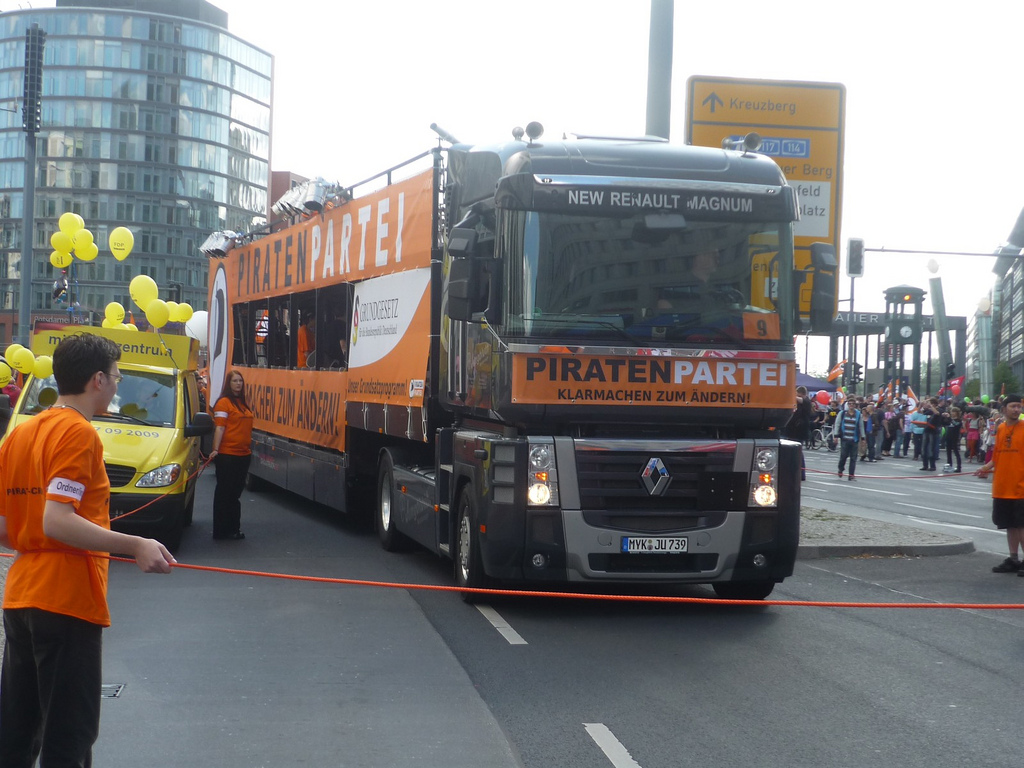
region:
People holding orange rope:
[2, 328, 1021, 766]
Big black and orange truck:
[190, 109, 848, 622]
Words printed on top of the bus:
[557, 185, 766, 217]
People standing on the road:
[803, 374, 997, 492]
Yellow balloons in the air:
[0, 207, 197, 404]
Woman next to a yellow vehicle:
[0, 318, 260, 556]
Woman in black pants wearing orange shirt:
[204, 366, 258, 544]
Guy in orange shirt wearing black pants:
[0, 328, 179, 766]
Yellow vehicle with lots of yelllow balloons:
[0, 208, 222, 557]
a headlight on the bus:
[752, 478, 787, 508]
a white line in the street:
[562, 700, 620, 759]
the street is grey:
[723, 683, 821, 763]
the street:
[715, 645, 896, 735]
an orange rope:
[452, 569, 621, 624]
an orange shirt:
[7, 431, 71, 488]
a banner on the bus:
[518, 355, 787, 401]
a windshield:
[538, 207, 767, 344]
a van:
[124, 365, 191, 480]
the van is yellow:
[135, 374, 196, 474]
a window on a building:
[57, 39, 76, 65]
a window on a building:
[88, 33, 102, 60]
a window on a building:
[107, 29, 126, 69]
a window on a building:
[126, 41, 146, 71]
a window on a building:
[43, 73, 54, 102]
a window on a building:
[53, 80, 76, 97]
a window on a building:
[98, 107, 111, 130]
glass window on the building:
[27, 36, 56, 59]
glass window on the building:
[35, 93, 45, 122]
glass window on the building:
[24, 125, 47, 155]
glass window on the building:
[24, 159, 37, 179]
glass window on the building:
[26, 185, 36, 212]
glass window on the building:
[29, 185, 40, 209]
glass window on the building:
[64, 90, 83, 126]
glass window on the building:
[95, 128, 114, 158]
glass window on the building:
[96, 161, 115, 187]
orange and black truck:
[196, 115, 810, 621]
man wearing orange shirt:
[0, 327, 178, 767]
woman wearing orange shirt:
[199, 372, 258, 547]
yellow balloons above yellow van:
[0, 202, 210, 553]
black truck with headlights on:
[186, 113, 815, 614]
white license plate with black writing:
[617, 532, 688, 562]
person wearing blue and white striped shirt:
[829, 394, 869, 472]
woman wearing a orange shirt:
[206, 389, 254, 470]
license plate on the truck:
[612, 527, 707, 562]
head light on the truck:
[521, 477, 560, 512]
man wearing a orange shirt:
[960, 417, 1022, 513]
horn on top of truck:
[698, 123, 769, 168]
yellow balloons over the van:
[46, 190, 190, 331]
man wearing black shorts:
[983, 496, 1022, 528]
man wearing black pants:
[8, 594, 122, 766]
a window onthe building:
[176, 157, 219, 195]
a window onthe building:
[139, 222, 172, 262]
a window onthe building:
[143, 113, 205, 175]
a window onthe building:
[257, 167, 270, 186]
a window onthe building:
[54, 112, 93, 173]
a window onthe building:
[80, 81, 118, 132]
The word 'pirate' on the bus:
[517, 354, 650, 389]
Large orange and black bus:
[179, 121, 810, 612]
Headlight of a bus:
[514, 434, 560, 508]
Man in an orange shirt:
[2, 325, 179, 765]